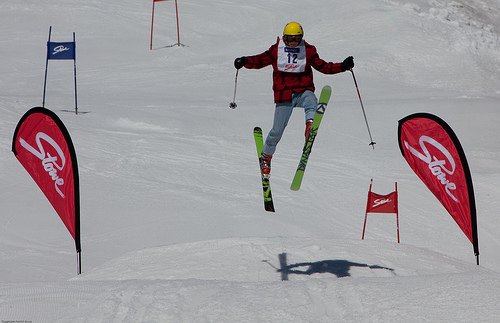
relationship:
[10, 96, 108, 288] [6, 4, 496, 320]
flags in snow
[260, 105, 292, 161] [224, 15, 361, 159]
leg of person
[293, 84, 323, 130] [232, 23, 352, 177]
leg of person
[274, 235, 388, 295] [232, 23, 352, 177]
shadow of person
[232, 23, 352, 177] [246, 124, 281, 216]
person wearing ski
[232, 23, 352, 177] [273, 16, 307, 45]
person wearing helmet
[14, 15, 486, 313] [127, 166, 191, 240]
ground covered n snow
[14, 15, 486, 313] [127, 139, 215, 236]
ground covered n snow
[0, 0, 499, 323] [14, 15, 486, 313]
snow covered n ground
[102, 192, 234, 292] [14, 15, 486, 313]
snow covered n ground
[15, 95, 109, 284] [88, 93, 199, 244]
banner in snow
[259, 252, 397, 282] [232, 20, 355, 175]
shadow of person